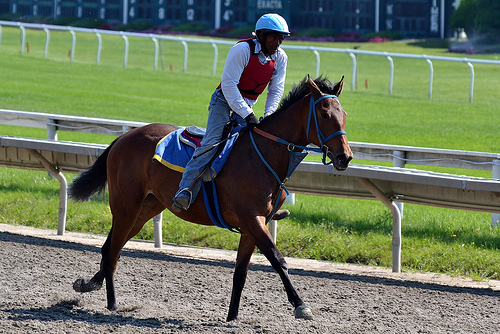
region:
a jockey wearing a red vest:
[218, 10, 286, 121]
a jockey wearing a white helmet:
[245, 5, 286, 65]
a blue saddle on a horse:
[149, 117, 237, 180]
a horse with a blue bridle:
[293, 79, 353, 174]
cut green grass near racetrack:
[13, 56, 164, 106]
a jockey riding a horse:
[164, 8, 308, 219]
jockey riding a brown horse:
[138, 28, 356, 243]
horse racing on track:
[76, 32, 353, 324]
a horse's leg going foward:
[245, 218, 319, 316]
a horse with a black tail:
[56, 130, 133, 204]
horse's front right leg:
[255, 242, 332, 325]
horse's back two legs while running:
[48, 199, 168, 319]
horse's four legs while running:
[45, 206, 347, 327]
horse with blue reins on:
[285, 70, 371, 186]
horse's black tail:
[60, 136, 107, 206]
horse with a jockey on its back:
[56, 5, 356, 328]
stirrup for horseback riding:
[170, 179, 199, 216]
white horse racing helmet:
[252, 8, 296, 36]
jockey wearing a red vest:
[166, 7, 295, 216]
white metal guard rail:
[374, 159, 499, 286]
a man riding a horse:
[61, 13, 348, 326]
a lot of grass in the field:
[11, 60, 141, 108]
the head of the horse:
[301, 75, 356, 172]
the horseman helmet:
[254, 12, 286, 34]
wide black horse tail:
[67, 136, 107, 198]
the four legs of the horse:
[81, 210, 314, 323]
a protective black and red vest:
[244, 48, 274, 102]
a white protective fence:
[3, 19, 198, 70]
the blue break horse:
[293, 94, 349, 169]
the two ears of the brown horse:
[304, 75, 346, 97]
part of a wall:
[466, 178, 476, 189]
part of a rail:
[411, 175, 435, 228]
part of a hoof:
[298, 310, 307, 327]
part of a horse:
[339, 138, 354, 185]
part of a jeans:
[210, 149, 215, 158]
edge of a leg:
[278, 252, 282, 267]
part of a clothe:
[200, 183, 202, 187]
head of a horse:
[336, 117, 341, 143]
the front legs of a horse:
[215, 215, 310, 320]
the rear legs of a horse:
[50, 195, 155, 310]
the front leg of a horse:
[250, 215, 330, 315]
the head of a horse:
[291, 65, 351, 175]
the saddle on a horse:
[174, 118, 245, 153]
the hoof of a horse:
[291, 304, 316, 319]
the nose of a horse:
[324, 137, 354, 172]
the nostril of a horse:
[332, 150, 344, 162]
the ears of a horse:
[304, 70, 346, 99]